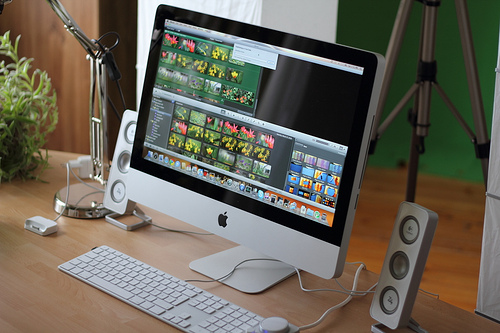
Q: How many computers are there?
A: One.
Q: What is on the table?
A: The computer.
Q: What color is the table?
A: Brown.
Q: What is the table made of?
A: Wood.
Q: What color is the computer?
A: White and black.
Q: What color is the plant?
A: Green.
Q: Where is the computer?
A: On the table.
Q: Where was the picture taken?
A: On the desk.